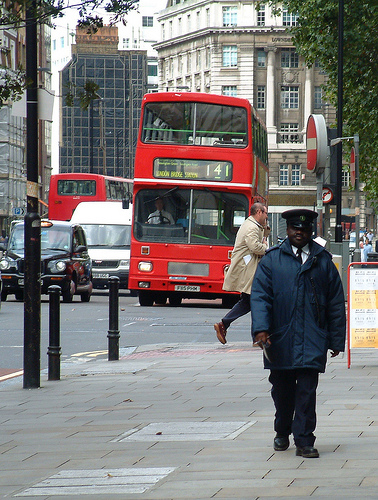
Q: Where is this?
A: This is at the sidewalk.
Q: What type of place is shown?
A: It is a sidewalk.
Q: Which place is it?
A: It is a sidewalk.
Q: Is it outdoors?
A: Yes, it is outdoors.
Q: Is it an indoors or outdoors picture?
A: It is outdoors.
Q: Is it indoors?
A: No, it is outdoors.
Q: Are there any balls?
A: No, there are no balls.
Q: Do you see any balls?
A: No, there are no balls.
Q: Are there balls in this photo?
A: No, there are no balls.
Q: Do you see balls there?
A: No, there are no balls.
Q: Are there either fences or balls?
A: No, there are no balls or fences.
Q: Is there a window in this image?
A: Yes, there is a window.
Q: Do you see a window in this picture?
A: Yes, there is a window.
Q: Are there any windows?
A: Yes, there is a window.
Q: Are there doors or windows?
A: Yes, there is a window.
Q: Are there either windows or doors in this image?
A: Yes, there is a window.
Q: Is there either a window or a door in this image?
A: Yes, there is a window.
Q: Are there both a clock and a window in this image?
A: No, there is a window but no clocks.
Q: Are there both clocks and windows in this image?
A: No, there is a window but no clocks.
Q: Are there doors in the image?
A: No, there are no doors.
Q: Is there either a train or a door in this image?
A: No, there are no doors or trains.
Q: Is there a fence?
A: No, there are no fences.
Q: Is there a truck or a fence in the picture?
A: No, there are no fences or trucks.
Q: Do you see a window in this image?
A: Yes, there is a window.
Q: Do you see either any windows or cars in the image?
A: Yes, there is a window.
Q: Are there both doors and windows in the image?
A: No, there is a window but no doors.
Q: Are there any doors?
A: No, there are no doors.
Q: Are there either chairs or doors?
A: No, there are no doors or chairs.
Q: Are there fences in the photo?
A: No, there are no fences.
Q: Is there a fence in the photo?
A: No, there are no fences.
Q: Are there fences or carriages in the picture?
A: No, there are no fences or carriages.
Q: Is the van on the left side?
A: Yes, the van is on the left of the image.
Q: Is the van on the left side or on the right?
A: The van is on the left of the image.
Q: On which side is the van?
A: The van is on the left of the image.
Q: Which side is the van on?
A: The van is on the left of the image.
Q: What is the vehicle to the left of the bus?
A: The vehicle is a van.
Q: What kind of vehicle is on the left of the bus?
A: The vehicle is a van.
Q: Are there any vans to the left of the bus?
A: Yes, there is a van to the left of the bus.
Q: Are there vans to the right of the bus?
A: No, the van is to the left of the bus.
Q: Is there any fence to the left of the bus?
A: No, there is a van to the left of the bus.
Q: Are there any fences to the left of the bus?
A: No, there is a van to the left of the bus.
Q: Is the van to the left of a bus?
A: Yes, the van is to the left of a bus.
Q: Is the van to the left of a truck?
A: No, the van is to the left of a bus.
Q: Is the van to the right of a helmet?
A: No, the van is to the right of a car.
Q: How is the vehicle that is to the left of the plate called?
A: The vehicle is a van.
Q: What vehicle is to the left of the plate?
A: The vehicle is a van.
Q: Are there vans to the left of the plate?
A: Yes, there is a van to the left of the plate.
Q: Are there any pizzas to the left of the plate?
A: No, there is a van to the left of the plate.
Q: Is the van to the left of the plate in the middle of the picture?
A: Yes, the van is to the left of the plate.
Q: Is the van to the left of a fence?
A: No, the van is to the left of the plate.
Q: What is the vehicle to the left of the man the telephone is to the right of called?
A: The vehicle is a van.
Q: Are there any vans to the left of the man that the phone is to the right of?
A: Yes, there is a van to the left of the man.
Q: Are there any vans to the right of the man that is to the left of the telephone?
A: No, the van is to the left of the man.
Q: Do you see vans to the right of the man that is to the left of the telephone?
A: No, the van is to the left of the man.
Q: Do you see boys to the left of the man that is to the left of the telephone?
A: No, there is a van to the left of the man.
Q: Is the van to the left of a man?
A: Yes, the van is to the left of a man.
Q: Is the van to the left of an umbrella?
A: No, the van is to the left of a man.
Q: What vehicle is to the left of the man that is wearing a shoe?
A: The vehicle is a van.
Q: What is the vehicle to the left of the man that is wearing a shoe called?
A: The vehicle is a van.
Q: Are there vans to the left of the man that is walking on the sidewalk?
A: Yes, there is a van to the left of the man.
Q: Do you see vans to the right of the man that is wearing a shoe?
A: No, the van is to the left of the man.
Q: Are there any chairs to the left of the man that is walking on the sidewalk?
A: No, there is a van to the left of the man.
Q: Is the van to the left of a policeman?
A: No, the van is to the left of a man.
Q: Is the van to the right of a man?
A: No, the van is to the left of a man.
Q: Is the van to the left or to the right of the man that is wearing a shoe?
A: The van is to the left of the man.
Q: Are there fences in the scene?
A: No, there are no fences.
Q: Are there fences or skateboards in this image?
A: No, there are no fences or skateboards.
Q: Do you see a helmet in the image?
A: No, there are no helmets.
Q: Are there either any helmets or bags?
A: No, there are no helmets or bags.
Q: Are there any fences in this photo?
A: No, there are no fences.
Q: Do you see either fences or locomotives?
A: No, there are no fences or locomotives.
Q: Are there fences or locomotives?
A: No, there are no fences or locomotives.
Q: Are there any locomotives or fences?
A: No, there are no fences or locomotives.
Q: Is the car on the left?
A: Yes, the car is on the left of the image.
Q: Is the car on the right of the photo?
A: No, the car is on the left of the image.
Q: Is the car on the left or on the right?
A: The car is on the left of the image.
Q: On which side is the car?
A: The car is on the left of the image.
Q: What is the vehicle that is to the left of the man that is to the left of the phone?
A: The vehicle is a car.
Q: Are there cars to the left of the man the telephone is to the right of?
A: Yes, there is a car to the left of the man.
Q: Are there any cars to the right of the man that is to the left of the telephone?
A: No, the car is to the left of the man.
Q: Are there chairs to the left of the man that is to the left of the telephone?
A: No, there is a car to the left of the man.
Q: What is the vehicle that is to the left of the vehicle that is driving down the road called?
A: The vehicle is a car.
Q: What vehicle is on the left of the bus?
A: The vehicle is a car.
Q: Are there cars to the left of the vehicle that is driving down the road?
A: Yes, there is a car to the left of the bus.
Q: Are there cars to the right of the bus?
A: No, the car is to the left of the bus.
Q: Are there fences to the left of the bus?
A: No, there is a car to the left of the bus.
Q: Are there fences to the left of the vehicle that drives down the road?
A: No, there is a car to the left of the bus.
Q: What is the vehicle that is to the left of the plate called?
A: The vehicle is a car.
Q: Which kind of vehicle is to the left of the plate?
A: The vehicle is a car.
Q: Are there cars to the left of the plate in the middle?
A: Yes, there is a car to the left of the plate.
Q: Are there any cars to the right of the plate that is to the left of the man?
A: No, the car is to the left of the plate.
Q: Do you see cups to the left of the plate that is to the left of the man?
A: No, there is a car to the left of the plate.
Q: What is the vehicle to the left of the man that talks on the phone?
A: The vehicle is a car.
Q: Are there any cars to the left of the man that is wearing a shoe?
A: Yes, there is a car to the left of the man.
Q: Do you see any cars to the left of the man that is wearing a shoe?
A: Yes, there is a car to the left of the man.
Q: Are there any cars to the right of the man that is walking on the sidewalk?
A: No, the car is to the left of the man.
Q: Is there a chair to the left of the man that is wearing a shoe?
A: No, there is a car to the left of the man.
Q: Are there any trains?
A: No, there are no trains.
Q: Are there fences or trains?
A: No, there are no trains or fences.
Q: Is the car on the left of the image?
A: Yes, the car is on the left of the image.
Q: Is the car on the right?
A: No, the car is on the left of the image.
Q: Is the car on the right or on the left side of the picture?
A: The car is on the left of the image.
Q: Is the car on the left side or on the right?
A: The car is on the left of the image.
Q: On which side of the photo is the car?
A: The car is on the left of the image.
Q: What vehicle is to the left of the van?
A: The vehicle is a car.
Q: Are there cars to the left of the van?
A: Yes, there is a car to the left of the van.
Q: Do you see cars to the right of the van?
A: No, the car is to the left of the van.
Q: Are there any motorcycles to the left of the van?
A: No, there is a car to the left of the van.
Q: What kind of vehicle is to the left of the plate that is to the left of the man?
A: The vehicle is a car.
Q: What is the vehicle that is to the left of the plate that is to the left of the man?
A: The vehicle is a car.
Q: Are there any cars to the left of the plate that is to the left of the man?
A: Yes, there is a car to the left of the plate.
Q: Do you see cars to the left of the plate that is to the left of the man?
A: Yes, there is a car to the left of the plate.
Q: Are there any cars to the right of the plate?
A: No, the car is to the left of the plate.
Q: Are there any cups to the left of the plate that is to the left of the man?
A: No, there is a car to the left of the plate.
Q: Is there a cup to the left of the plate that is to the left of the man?
A: No, there is a car to the left of the plate.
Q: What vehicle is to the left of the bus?
A: The vehicle is a car.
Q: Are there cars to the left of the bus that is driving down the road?
A: Yes, there is a car to the left of the bus.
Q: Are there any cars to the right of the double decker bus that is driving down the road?
A: No, the car is to the left of the bus.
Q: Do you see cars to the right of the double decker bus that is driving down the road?
A: No, the car is to the left of the bus.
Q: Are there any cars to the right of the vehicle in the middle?
A: No, the car is to the left of the bus.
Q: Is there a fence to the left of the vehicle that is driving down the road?
A: No, there is a car to the left of the bus.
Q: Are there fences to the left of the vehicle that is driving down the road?
A: No, there is a car to the left of the bus.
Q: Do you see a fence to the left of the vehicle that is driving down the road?
A: No, there is a car to the left of the bus.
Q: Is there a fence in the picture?
A: No, there are no fences.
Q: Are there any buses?
A: Yes, there is a bus.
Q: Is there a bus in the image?
A: Yes, there is a bus.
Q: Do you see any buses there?
A: Yes, there is a bus.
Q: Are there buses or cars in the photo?
A: Yes, there is a bus.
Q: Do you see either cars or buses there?
A: Yes, there is a bus.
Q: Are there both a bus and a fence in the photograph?
A: No, there is a bus but no fences.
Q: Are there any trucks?
A: No, there are no trucks.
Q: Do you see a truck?
A: No, there are no trucks.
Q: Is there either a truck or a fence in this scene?
A: No, there are no trucks or fences.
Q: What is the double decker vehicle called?
A: The vehicle is a bus.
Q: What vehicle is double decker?
A: The vehicle is a bus.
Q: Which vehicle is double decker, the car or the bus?
A: The bus is double decker.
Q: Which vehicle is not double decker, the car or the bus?
A: The car is not double decker.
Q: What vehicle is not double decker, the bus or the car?
A: The car is not double decker.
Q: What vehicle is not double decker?
A: The vehicle is a car.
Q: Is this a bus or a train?
A: This is a bus.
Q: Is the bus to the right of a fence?
A: No, the bus is to the right of a car.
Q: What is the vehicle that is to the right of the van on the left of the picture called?
A: The vehicle is a bus.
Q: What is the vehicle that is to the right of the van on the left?
A: The vehicle is a bus.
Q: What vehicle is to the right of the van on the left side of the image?
A: The vehicle is a bus.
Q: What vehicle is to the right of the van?
A: The vehicle is a bus.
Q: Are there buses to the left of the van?
A: No, the bus is to the right of the van.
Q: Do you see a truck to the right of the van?
A: No, there is a bus to the right of the van.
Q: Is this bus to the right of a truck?
A: No, the bus is to the right of a van.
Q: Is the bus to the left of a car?
A: No, the bus is to the right of a car.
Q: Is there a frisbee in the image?
A: No, there are no frisbees.